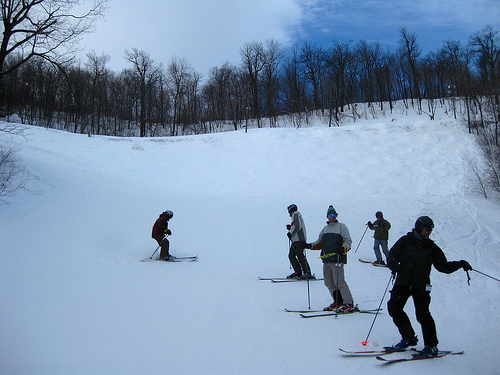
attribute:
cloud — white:
[0, 1, 307, 86]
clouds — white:
[3, 1, 312, 77]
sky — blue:
[1, 0, 485, 95]